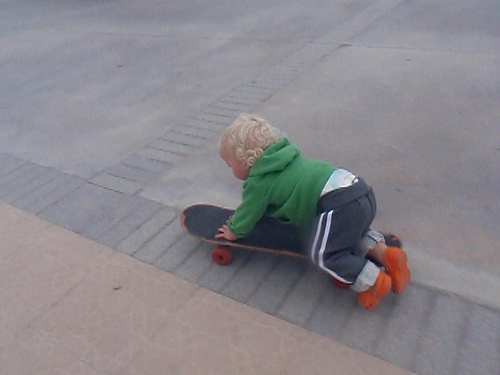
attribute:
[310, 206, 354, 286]
stripes — white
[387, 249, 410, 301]
shoe — orange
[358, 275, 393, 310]
shoe — orange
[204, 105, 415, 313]
child — small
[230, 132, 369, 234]
hoodie — green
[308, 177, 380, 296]
pants — black, white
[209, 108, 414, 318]
boy — little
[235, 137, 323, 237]
hoodie — green